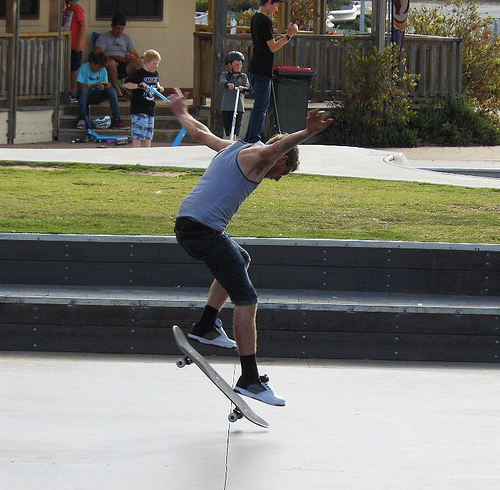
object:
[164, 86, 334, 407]
person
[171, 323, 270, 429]
skateboard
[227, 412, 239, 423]
wheel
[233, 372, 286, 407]
shoe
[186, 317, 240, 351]
shoe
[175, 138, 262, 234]
tank top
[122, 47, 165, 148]
child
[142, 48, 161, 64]
hair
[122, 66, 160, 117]
shirt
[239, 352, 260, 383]
socks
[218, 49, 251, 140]
boy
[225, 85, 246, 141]
scooter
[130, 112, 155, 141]
shorts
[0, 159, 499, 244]
area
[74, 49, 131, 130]
boy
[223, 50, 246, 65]
helmet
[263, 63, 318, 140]
garbage can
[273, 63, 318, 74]
lid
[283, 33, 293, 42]
watch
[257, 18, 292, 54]
arm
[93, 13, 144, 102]
man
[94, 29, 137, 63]
shirt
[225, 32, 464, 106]
rail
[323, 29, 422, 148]
shrub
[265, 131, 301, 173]
hair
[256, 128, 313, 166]
arms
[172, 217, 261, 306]
shorts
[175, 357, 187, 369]
wheels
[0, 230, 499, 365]
wall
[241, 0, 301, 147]
man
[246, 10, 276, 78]
shirt